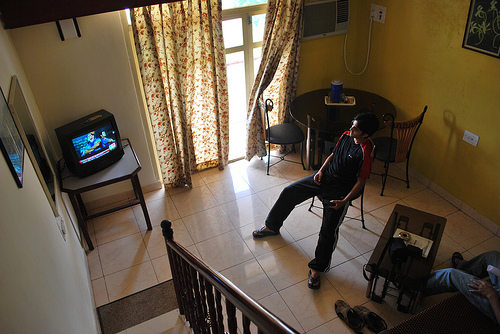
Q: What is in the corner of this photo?
A: A table.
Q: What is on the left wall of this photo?
A: Two pictures.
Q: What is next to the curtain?
A: An air conditioner.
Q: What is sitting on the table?
A: A television.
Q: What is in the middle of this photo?
A: A person sitting in a chair.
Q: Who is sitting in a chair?
A: A man.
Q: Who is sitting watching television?
A: A man.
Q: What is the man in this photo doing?
A: Watching a television.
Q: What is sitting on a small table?
A: A television.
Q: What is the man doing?
A: Sitting?.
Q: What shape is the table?
A: Circle.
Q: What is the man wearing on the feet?
A: Flip flops.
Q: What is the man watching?
A: A television.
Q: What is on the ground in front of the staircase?
A: A rug.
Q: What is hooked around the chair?
A: A curtain.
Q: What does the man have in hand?
A: A remote.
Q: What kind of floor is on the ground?
A: Tile.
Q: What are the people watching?
A: Television.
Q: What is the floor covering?
A: Tile.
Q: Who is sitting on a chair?
A: A man.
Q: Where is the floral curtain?
A: On window.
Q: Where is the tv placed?
A: On table.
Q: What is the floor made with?
A: Tiles.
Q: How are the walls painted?
A: Mustard yellow.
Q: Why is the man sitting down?
A: Watching tv.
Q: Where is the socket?
A: Right wall.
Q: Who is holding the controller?
A: Person on the couch.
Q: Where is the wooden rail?
A: On staircase.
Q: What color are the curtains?
A: Brown and red.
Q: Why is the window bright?
A: The sun is shining.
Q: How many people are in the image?
A: Two.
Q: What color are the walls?
A: Yellow.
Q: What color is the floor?
A: White.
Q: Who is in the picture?
A: Two people.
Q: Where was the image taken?
A: On stairs.